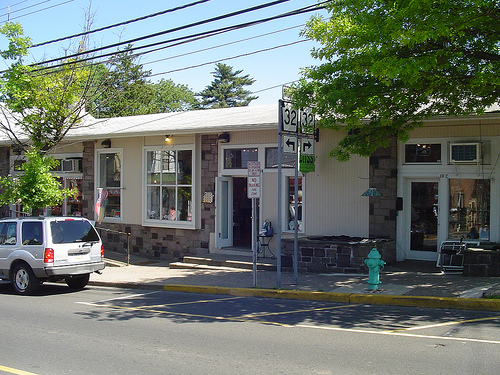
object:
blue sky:
[7, 0, 322, 59]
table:
[257, 219, 275, 260]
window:
[142, 144, 202, 231]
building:
[0, 95, 497, 266]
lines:
[76, 289, 500, 344]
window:
[220, 144, 261, 175]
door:
[214, 177, 234, 248]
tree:
[0, 17, 105, 214]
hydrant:
[363, 248, 387, 290]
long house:
[0, 97, 500, 272]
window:
[94, 148, 123, 222]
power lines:
[0, 0, 346, 80]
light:
[163, 135, 173, 144]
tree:
[295, 0, 500, 162]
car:
[0, 216, 105, 296]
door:
[405, 177, 441, 261]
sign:
[282, 103, 299, 133]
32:
[284, 109, 297, 126]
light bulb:
[165, 138, 170, 142]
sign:
[300, 137, 314, 154]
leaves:
[6, 145, 76, 208]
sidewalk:
[91, 251, 499, 304]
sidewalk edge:
[167, 285, 498, 310]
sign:
[245, 161, 263, 198]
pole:
[251, 198, 257, 286]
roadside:
[2, 273, 497, 373]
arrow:
[303, 141, 312, 152]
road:
[0, 260, 500, 375]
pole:
[294, 102, 298, 285]